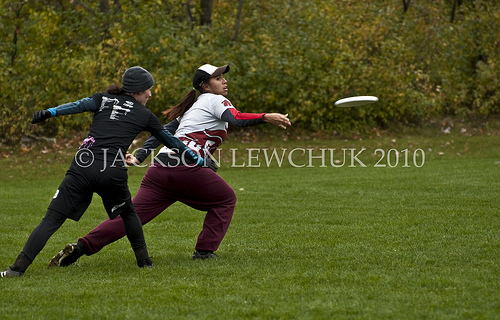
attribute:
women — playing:
[9, 48, 236, 280]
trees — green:
[2, 2, 499, 141]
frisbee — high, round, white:
[330, 91, 381, 111]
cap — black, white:
[192, 61, 229, 89]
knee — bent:
[217, 187, 238, 212]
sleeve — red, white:
[206, 97, 232, 118]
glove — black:
[27, 110, 49, 126]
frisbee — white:
[334, 95, 379, 106]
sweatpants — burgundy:
[77, 162, 237, 252]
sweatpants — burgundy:
[47, 159, 236, 267]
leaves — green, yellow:
[1, 3, 498, 123]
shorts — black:
[46, 160, 132, 219]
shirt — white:
[153, 90, 242, 154]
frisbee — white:
[326, 88, 385, 110]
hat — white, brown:
[191, 59, 232, 87]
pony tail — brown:
[156, 90, 195, 126]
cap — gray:
[118, 60, 157, 90]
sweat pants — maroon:
[68, 151, 240, 256]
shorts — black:
[44, 145, 137, 223]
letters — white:
[96, 94, 137, 129]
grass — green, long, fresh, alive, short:
[2, 142, 483, 318]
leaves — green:
[248, 27, 359, 76]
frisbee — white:
[322, 92, 386, 112]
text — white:
[97, 143, 223, 174]